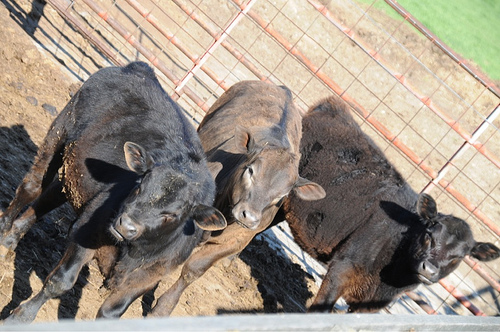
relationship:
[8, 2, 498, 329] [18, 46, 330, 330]
fence around cow area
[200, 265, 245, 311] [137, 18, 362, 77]
ground behind cage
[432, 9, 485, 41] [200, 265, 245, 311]
grass on ground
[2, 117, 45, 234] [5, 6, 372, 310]
shadow on ground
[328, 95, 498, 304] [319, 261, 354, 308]
cow has leg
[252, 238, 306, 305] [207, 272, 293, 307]
shadow on dirt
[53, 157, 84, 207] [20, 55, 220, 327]
mud on cow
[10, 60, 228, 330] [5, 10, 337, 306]
cow on ground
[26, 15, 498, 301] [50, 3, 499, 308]
rail attached to fence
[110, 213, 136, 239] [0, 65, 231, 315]
nose on cow